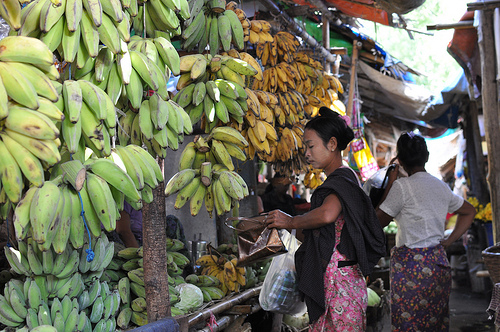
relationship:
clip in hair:
[336, 112, 352, 126] [303, 105, 355, 150]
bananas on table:
[90, 294, 106, 323] [132, 284, 270, 330]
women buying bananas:
[259, 102, 370, 329] [92, 164, 144, 208]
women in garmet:
[259, 102, 370, 329] [307, 217, 369, 330]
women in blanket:
[259, 102, 370, 329] [285, 166, 386, 323]